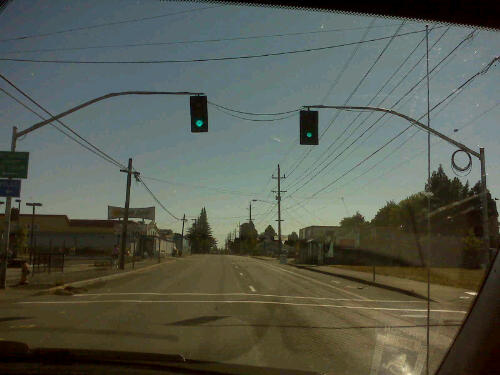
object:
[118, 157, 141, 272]
metal pole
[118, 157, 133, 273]
pole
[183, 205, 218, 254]
tree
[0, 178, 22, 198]
sign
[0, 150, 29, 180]
sign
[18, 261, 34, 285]
fire hydrant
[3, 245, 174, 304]
sidewalk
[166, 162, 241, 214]
clouds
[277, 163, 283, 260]
pole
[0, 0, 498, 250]
clear sky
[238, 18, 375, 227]
wires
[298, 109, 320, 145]
sign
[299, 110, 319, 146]
light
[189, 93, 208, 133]
stop light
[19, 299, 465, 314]
lines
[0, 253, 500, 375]
road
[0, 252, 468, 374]
street